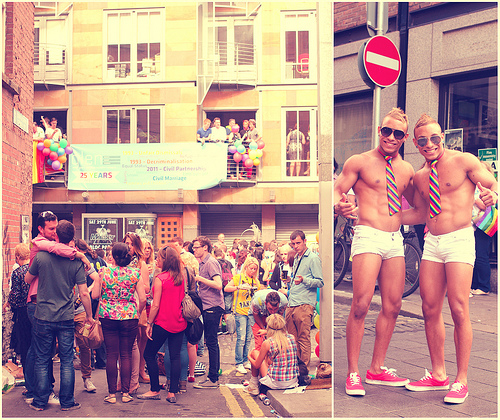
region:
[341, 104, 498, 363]
two guys with no shirts on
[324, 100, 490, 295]
two guys wearing white shorts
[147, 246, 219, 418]
lady in black pants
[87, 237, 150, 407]
lady wearing sleeveless flowered top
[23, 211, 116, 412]
two people hugging each other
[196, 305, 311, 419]
person sitting on the curb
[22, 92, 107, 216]
balloons hanging from balcony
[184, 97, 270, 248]
people standing on balcony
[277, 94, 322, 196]
person in window of building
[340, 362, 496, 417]
red and white canvas shoes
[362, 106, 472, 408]
two men wearing white shorts and striped neckties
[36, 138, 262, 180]
two bunches of balloons and a banner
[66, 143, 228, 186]
white banner hanging from balconies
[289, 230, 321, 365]
man wearing a blue shirt and brown pants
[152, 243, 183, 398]
woman wearing blue jeans and a red sleeveless shirt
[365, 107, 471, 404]
two men wearing red shoes and sunglasses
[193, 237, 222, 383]
man wearing a glasses, a purple shirt and dark jeans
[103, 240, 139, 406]
woman with brown hair wearing a floral patterned shirt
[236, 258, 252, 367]
blond woman wearing jeans and a yellow shirt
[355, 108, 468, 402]
two men wearing matching shoes, shorts, and ties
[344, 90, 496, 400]
two men tanding on the sidewalk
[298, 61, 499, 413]
two men standing togehter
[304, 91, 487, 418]
two men posing togehter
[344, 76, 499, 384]
two men smiling togehter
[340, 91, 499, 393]
two men that are smiling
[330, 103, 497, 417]
two men with blonde hair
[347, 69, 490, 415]
men that are smiling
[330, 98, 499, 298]
men with blonde hair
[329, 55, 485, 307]
men wearing sunglasses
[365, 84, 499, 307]
men wearing ties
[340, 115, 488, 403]
two shirtless men posing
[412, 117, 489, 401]
shirtless man wearing a colorful tie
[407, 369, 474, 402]
man wearing pink shoes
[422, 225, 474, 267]
white shorts on a man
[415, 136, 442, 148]
sunglasses on a man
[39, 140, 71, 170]
colorful decorative balloons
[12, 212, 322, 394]
a crowd of people on the street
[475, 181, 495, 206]
a man giving a thumbs up sign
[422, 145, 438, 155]
the smile on a man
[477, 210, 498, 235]
a rainbow colored bag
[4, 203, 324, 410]
A crowd of people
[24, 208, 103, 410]
Two men embracing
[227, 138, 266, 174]
Balloons on a balcony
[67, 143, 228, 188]
A banner celebrating marriage equality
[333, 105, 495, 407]
Two men dressed alike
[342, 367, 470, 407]
Four red sneakers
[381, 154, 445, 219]
Two striped neckties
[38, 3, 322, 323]
Three stories of an apartment building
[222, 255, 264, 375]
A blonde girl with a yellow shirt and jeans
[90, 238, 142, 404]
A women in a flowered shirt